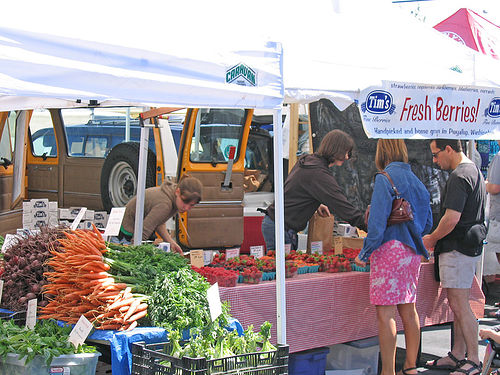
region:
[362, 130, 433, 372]
woman wearing blue shirt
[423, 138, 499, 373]
man wearing short sleeve black shirt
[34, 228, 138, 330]
pile of orange carrots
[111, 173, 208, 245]
person wearing brown jacket bending over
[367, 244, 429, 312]
pink and white skirt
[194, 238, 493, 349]
table with red tablecloth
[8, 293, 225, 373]
blue tablecloth on table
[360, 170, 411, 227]
brown purse of woman in blue shirt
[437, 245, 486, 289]
biege pants of man in black shirt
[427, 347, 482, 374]
black sandals of man in black shirt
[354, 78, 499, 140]
a sign for Tim's Fresh Berries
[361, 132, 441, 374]
a woman in a jean jacket and pink skirt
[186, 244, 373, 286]
fresh berries on the table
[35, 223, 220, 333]
a bunch of carrots on the table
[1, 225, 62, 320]
a bunch of radishes on the table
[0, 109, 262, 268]
a yellow van with doors open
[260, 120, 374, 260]
a woman helping customers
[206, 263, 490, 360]
a red checkered table cloth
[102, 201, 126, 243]
a small sign for the vegetables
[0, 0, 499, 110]
a tent covering the vegetable stand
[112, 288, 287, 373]
a cart full of green vegtables.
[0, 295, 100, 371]
a light blue crate full of vegtables.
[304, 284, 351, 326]
a pink and white table cloth.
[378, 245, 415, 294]
a woman is wearing a pink and white shirt.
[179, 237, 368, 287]
a table full of strawberries.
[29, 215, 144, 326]
a bid stack of carrots.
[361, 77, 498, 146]
a sign says Tims fresh berries.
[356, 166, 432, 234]
a woman is carrying a brown shoulder bag.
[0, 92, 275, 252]
a orange and brown truck.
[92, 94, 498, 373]
the people are buying vegetables.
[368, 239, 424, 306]
pink skirt with large white spots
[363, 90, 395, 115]
blue circle with the word "Tim's" in white letters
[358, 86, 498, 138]
banner declaring Fresh Berries!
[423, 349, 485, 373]
white male feet wearing black sandals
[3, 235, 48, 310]
large stack of red potatoes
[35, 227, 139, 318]
tight pile of orange-brown carrots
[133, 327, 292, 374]
black plastic crate filled with green vegetables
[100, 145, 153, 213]
spare tire attached to side of van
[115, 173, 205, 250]
woman bending over picking up produce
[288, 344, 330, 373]
blue plastic lidded square tote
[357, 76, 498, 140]
a red, white and blue sign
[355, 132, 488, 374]
a man and a woman in front of table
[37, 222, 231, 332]
a pile of carrots with green tops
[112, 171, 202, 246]
a woman wearing a brown hoodie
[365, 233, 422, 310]
a woman wearing pink and white skirt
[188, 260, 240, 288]
a container of tomatoes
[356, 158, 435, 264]
a woman wearing a blue shirt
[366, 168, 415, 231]
a woman wearing a brown purse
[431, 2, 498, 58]
top of red tent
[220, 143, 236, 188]
a silver handle with a red tip